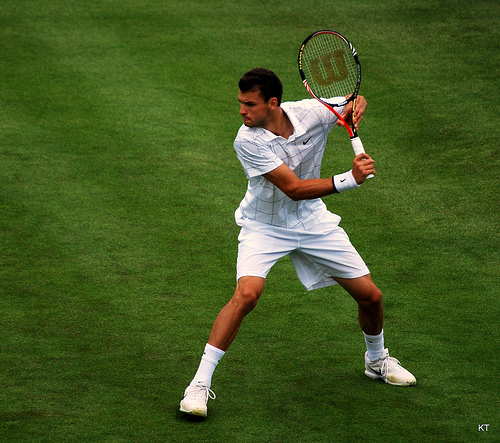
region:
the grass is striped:
[0, 3, 495, 438]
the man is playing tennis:
[155, 34, 430, 431]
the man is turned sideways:
[87, 33, 445, 425]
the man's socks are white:
[151, 279, 414, 406]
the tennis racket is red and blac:
[281, 29, 369, 141]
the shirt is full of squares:
[211, 120, 357, 235]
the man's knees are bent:
[190, 240, 464, 384]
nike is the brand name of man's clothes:
[290, 128, 364, 215]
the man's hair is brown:
[233, 67, 298, 110]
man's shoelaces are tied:
[173, 367, 240, 420]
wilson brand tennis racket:
[292, 22, 402, 196]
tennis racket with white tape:
[294, 24, 396, 186]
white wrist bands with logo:
[322, 160, 362, 201]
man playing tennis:
[164, 24, 422, 419]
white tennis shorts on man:
[224, 208, 396, 293]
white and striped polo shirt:
[215, 98, 355, 236]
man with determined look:
[235, 61, 286, 133]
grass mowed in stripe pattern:
[32, 90, 183, 291]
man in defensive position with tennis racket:
[158, 24, 432, 424]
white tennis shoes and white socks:
[161, 328, 239, 420]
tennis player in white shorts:
[177, 27, 415, 416]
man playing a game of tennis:
[12, 28, 490, 419]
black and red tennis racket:
[296, 27, 376, 185]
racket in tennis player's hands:
[296, 30, 376, 185]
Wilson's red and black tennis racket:
[296, 29, 374, 153]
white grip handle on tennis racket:
[350, 137, 375, 179]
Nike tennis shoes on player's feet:
[179, 347, 417, 417]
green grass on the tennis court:
[15, 129, 185, 319]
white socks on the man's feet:
[188, 326, 383, 381]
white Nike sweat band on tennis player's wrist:
[330, 167, 362, 194]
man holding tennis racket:
[176, 25, 421, 425]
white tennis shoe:
[177, 376, 219, 421]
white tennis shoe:
[361, 349, 422, 390]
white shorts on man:
[235, 205, 372, 285]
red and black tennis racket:
[296, 25, 378, 184]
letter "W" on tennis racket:
[307, 45, 351, 89]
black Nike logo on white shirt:
[298, 131, 318, 148]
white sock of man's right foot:
[188, 338, 230, 385]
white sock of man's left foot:
[358, 327, 389, 360]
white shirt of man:
[230, 91, 348, 228]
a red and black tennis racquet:
[297, 29, 386, 178]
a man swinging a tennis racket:
[179, 27, 429, 422]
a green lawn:
[2, 1, 499, 440]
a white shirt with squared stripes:
[221, 102, 375, 242]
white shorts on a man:
[208, 196, 391, 282]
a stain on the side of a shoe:
[382, 371, 398, 387]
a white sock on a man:
[189, 340, 239, 393]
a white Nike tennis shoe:
[362, 346, 429, 396]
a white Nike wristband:
[329, 165, 375, 200]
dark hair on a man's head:
[235, 66, 290, 109]